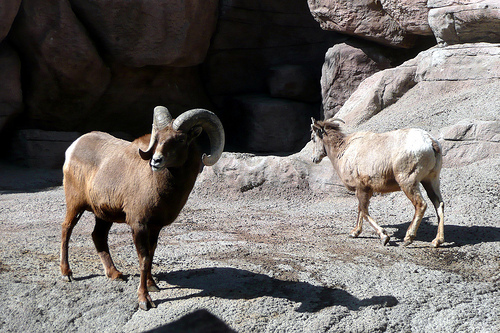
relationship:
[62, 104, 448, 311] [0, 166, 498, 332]
animals on ground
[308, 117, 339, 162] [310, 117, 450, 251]
head of animal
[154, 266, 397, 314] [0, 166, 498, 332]
shadow on ground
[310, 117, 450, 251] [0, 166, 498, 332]
animal on ground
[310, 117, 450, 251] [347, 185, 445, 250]
animal has legs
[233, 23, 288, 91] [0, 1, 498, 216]
shadow on background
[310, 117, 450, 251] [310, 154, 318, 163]
animal has nose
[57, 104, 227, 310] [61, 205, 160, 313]
animals has legs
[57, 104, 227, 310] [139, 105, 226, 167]
animals has horns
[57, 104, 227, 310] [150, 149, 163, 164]
animals has nose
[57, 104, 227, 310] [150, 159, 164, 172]
animals has mouth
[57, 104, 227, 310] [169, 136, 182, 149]
animals has eye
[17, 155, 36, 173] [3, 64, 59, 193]
part of shade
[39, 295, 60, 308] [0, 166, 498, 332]
part of ground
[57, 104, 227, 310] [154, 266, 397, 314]
animals has shadow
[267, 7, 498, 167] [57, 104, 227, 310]
rocks behind animals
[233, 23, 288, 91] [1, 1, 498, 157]
shadow of wall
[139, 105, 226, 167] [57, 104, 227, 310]
horns on animals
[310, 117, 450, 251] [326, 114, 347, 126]
animal has horn